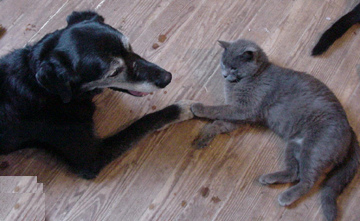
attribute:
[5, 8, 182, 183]
dog — black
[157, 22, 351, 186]
cat — gray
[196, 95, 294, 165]
legs — grey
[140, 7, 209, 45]
floor — brown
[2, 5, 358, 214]
flooring slats — surface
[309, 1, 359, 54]
tail — black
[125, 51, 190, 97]
mouth — slightly open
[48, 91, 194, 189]
leg — black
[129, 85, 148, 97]
tongue — pink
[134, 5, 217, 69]
floor — wooden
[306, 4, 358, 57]
tail — straight 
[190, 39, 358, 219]
gray cat — grey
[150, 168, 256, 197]
strips — wood